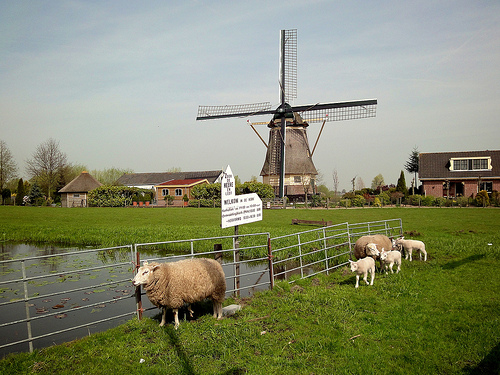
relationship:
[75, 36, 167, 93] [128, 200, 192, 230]
sky above land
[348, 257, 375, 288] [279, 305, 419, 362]
animal in grass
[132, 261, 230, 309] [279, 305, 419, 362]
adult in grass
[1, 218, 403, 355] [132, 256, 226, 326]
fence next to animal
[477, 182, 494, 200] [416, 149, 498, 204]
window on house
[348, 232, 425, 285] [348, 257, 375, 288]
group of animal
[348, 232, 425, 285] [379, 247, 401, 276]
group of sheep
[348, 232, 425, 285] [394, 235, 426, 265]
group of sheep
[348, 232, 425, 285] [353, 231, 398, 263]
group of sheep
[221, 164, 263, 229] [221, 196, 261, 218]
sign with lettering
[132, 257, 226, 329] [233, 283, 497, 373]
adult strolling in grass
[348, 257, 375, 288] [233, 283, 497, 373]
animal strolling in grass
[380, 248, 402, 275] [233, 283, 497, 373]
baby strolling in grass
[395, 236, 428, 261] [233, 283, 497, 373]
animal strolling in grass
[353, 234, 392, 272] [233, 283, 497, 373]
adult strolling in grass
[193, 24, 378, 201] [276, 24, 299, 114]
windmill and arm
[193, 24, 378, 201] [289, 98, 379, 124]
windmill and arm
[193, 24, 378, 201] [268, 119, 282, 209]
windmill and arm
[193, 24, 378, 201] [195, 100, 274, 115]
windmill and arm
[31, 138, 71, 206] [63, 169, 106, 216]
tree next to house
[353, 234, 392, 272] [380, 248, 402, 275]
adult nuzzling baby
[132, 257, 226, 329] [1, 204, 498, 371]
adult standing on grass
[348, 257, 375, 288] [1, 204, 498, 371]
animal standing on grass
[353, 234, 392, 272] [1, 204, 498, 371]
adult standing on grass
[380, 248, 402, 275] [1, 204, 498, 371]
baby standing on grass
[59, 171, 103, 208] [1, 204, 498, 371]
house standing on grass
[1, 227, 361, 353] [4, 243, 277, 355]
pond with water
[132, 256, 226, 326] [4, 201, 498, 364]
animal on ground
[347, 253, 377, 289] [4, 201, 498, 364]
animal on ground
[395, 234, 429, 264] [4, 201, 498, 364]
animal on ground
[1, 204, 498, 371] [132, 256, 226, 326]
grass next to animal